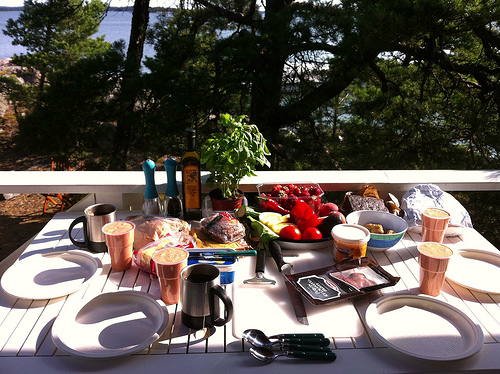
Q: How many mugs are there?
A: Two.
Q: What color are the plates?
A: White.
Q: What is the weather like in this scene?
A: It is sunny.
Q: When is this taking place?
A: During the daytime.